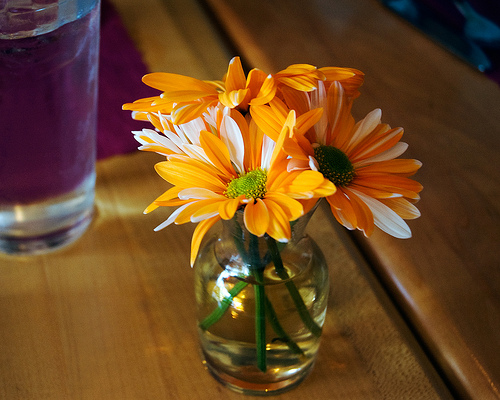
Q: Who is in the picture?
A: No one.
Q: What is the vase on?
A: A table.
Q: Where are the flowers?
A: In the vase.